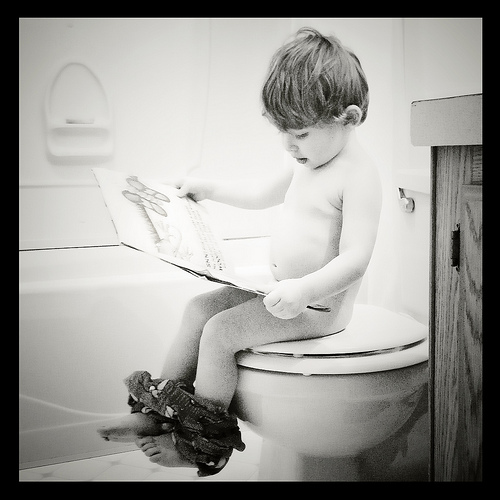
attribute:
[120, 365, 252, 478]
pants — down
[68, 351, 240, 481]
pants — down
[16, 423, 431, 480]
flooring — white, linoleum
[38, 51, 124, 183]
container — white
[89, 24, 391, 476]
toddler — reading, sitting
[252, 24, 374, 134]
hair — long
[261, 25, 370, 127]
hair — long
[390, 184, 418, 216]
handle — shiny, silver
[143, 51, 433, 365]
boy — shirtless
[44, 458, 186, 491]
floor — linoleum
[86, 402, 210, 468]
feet — bare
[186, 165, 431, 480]
toilet — shiny, white, porcelain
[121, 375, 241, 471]
pajama pants — little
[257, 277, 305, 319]
hand — little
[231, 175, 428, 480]
toilet — white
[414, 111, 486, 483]
cabinet — wood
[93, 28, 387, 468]
boy — little,  little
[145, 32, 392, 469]
boy — little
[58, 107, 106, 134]
soap — used, white